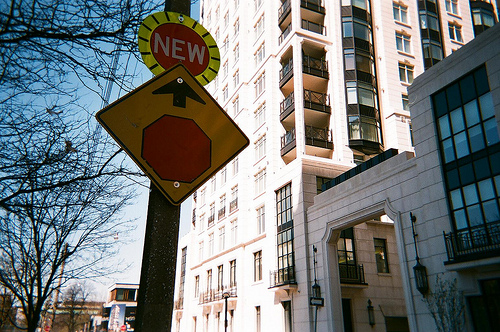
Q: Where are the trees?
A: On the left of the sign.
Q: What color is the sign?
A: Yellow.